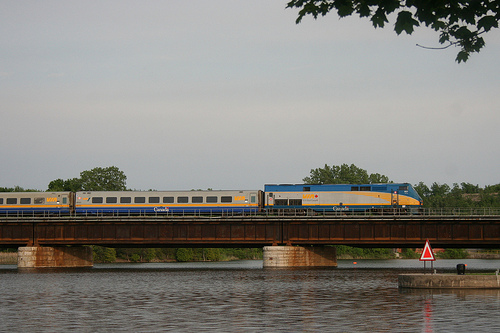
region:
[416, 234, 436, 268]
triangular sign with red and white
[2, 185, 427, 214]
blue yellow and silver train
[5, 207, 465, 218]
silver fencing along a rail road track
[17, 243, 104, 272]
brick pillar holding up a train over pass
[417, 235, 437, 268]
warning sign for boats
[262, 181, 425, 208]
lead car on a passenger train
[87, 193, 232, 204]
dark windows on a train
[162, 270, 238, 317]
ripples and waves in the water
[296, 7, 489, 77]
green leaves on a branch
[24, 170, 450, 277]
train going over a bridge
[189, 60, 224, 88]
the sky is light dark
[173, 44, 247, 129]
the sky is light dark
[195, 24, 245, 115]
the sky is light dark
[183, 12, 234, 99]
the sky is light dark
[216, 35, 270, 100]
the sky is light dark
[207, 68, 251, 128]
the sky is light dark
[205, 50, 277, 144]
the sky is light dark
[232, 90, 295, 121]
the sky is light dark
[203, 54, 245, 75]
the sky is light dark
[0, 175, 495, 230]
The train is traveling down the tracks.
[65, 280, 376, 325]
The water is slighlty brownish.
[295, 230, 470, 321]
A red sign is next to the water.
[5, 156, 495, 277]
The train is on a bridge over water.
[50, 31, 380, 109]
The sky is light blue.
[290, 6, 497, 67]
Some leaves on a tree.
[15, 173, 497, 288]
The train is next to the water.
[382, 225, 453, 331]
A reflection of the sign in the water.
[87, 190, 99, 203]
A window on the train.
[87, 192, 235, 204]
A row of windows on the train.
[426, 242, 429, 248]
the sign is red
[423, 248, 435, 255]
the sign is red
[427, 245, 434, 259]
the sign is red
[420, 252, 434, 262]
the sign is red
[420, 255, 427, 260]
the sign is red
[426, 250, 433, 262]
the sign is red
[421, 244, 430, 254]
the sign is red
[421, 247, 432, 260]
the sign is red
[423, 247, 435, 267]
the sign is red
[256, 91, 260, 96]
part of the sky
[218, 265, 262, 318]
part of a water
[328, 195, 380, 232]
edge of a bridge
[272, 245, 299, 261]
part of a stand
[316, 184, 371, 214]
side of a train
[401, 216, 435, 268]
part of a post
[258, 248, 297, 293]
part of a water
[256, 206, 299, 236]
edge of a bridge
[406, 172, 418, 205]
edge of a train